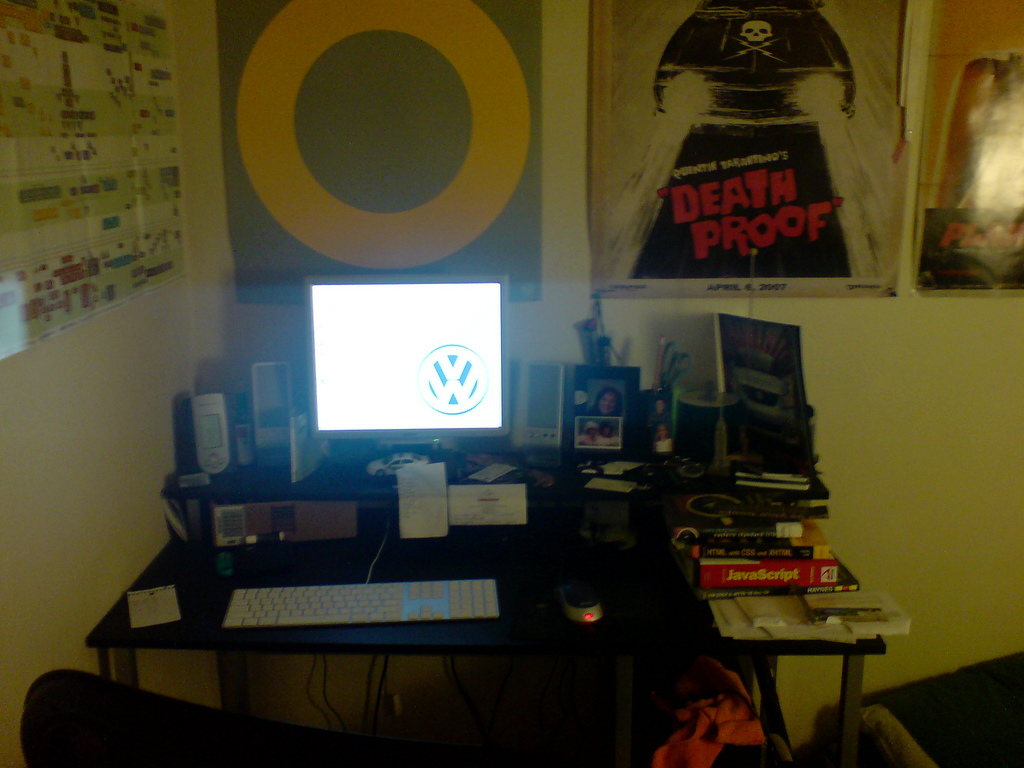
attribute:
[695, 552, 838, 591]
book binding — red, with yellow text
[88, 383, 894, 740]
black desk — against the wall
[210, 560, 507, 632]
keyboard — white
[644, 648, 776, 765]
bag — orange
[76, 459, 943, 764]
desk — black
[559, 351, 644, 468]
picture frame — black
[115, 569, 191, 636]
notepad — white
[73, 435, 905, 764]
table — small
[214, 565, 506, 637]
keyboard — white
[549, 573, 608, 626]
mouse — silver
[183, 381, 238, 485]
speaker — small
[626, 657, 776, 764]
cloth — orange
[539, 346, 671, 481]
picture — framed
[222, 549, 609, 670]
keyboard — white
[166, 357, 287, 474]
speaker — white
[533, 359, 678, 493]
picture frame — black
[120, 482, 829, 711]
desk — black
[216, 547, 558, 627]
keyboard — white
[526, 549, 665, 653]
mouse — black, gray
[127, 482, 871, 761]
desk — black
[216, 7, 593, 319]
picture — gray, hanging, yellow